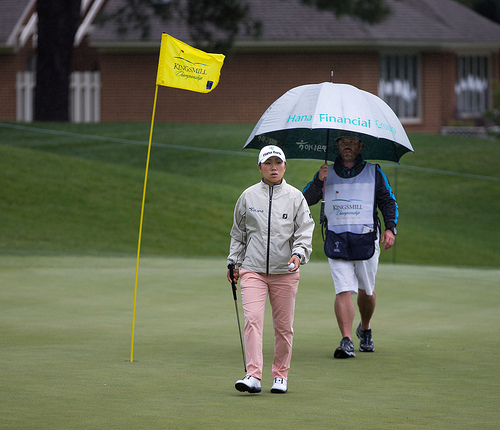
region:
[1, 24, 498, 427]
Two people walking on a golf course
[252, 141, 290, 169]
A hat is white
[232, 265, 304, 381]
The pants are pink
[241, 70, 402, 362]
Man is holding a big umbrella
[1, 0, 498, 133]
A brown building is in the background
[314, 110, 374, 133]
"Financial" written on an umbrella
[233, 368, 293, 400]
A pair of white shoes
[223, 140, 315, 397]
Woman is holding a golf club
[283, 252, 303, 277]
A golf ball in a hand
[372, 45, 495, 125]
Two windows on a building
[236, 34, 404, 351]
the man with umbrella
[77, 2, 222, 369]
the flag is yellow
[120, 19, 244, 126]
the flag is yellow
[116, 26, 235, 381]
flag on a golf course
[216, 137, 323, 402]
female golfer on the grass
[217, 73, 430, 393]
two people on a golf course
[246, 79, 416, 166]
umbrella held by a man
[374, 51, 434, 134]
window on a building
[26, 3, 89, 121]
trunk of a tree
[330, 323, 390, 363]
sneakers of a man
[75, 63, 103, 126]
white picket fence by tree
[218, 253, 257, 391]
golf club in woman's hand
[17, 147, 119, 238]
green grass at a golf course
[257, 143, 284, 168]
the woman is wearing a hat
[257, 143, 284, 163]
the hat is white in color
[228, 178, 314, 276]
the woman is wearing a jacket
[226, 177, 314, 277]
the jacket is white in color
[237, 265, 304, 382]
the woman is wearing long pants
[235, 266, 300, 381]
the pants are pink in color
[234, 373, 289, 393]
the woman is wearing sneakers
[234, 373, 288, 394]
the sneakers are white in color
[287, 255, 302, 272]
the woman is holding a ball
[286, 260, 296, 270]
the ball is white in color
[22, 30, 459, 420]
One person is carrying an umbrella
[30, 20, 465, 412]
The people are casual walking around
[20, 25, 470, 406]
The people are playing some golf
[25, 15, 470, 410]
Two people are walking together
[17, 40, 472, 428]
Two people are out in the daytime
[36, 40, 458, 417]
Two people are wearing nice hats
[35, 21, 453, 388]
Two people are on a golf course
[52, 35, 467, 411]
Two people are having some fun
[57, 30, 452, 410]
Two people are walking on the grass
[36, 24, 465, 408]
One person is carrying a golf ball